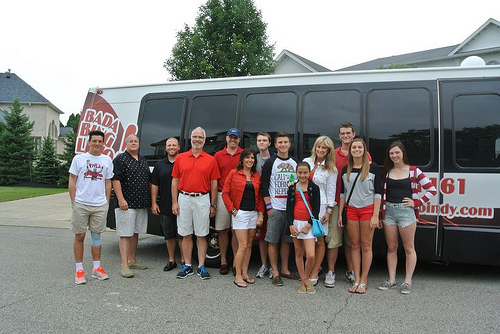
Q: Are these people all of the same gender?
A: No, they are both male and female.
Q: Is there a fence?
A: No, there are no fences.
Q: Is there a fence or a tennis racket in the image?
A: No, there are no fences or rackets.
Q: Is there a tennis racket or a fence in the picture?
A: No, there are no fences or rackets.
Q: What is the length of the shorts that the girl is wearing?
A: The shorts are short.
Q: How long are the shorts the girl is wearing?
A: The shorts are short.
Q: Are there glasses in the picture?
A: No, there are no glasses.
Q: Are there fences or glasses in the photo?
A: No, there are no glasses or fences.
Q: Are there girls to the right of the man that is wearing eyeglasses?
A: Yes, there is a girl to the right of the man.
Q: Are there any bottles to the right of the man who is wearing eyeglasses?
A: No, there is a girl to the right of the man.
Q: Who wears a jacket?
A: The girl wears a jacket.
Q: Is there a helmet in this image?
A: No, there are no helmets.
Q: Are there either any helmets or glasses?
A: No, there are no helmets or glasses.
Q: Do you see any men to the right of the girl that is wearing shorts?
A: Yes, there is a man to the right of the girl.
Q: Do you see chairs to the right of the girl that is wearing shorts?
A: No, there is a man to the right of the girl.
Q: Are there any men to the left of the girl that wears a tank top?
A: Yes, there is a man to the left of the girl.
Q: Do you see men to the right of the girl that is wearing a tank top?
A: No, the man is to the left of the girl.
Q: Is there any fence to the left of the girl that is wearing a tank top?
A: No, there is a man to the left of the girl.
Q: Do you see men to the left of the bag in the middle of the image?
A: Yes, there is a man to the left of the handbag.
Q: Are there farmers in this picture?
A: No, there are no farmers.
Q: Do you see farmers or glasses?
A: No, there are no farmers or glasses.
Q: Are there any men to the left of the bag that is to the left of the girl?
A: Yes, there is a man to the left of the handbag.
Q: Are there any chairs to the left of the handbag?
A: No, there is a man to the left of the handbag.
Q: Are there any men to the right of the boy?
A: Yes, there is a man to the right of the boy.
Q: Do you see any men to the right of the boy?
A: Yes, there is a man to the right of the boy.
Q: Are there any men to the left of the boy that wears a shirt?
A: No, the man is to the right of the boy.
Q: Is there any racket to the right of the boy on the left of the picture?
A: No, there is a man to the right of the boy.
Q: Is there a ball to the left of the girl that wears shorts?
A: No, there is a man to the left of the girl.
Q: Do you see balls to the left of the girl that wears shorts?
A: No, there is a man to the left of the girl.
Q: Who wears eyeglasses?
A: The man wears eyeglasses.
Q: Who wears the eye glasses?
A: The man wears eyeglasses.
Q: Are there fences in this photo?
A: No, there are no fences.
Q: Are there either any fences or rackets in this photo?
A: No, there are no fences or rackets.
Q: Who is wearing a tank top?
A: The girl is wearing a tank top.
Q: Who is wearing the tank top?
A: The girl is wearing a tank top.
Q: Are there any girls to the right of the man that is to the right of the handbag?
A: Yes, there is a girl to the right of the man.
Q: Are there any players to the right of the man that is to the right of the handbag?
A: No, there is a girl to the right of the man.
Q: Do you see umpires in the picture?
A: No, there are no umpires.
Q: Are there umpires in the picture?
A: No, there are no umpires.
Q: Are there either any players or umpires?
A: No, there are no umpires or players.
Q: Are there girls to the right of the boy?
A: Yes, there is a girl to the right of the boy.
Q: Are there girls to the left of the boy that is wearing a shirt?
A: No, the girl is to the right of the boy.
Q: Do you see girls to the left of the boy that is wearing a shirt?
A: No, the girl is to the right of the boy.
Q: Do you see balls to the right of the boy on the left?
A: No, there is a girl to the right of the boy.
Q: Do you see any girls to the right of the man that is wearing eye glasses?
A: Yes, there is a girl to the right of the man.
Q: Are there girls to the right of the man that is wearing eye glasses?
A: Yes, there is a girl to the right of the man.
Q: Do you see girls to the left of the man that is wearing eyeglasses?
A: No, the girl is to the right of the man.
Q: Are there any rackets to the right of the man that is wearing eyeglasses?
A: No, there is a girl to the right of the man.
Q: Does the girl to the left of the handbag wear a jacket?
A: Yes, the girl wears a jacket.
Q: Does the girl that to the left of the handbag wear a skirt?
A: No, the girl wears a jacket.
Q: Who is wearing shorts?
A: The girl is wearing shorts.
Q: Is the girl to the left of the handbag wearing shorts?
A: Yes, the girl is wearing shorts.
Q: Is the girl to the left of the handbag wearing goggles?
A: No, the girl is wearing shorts.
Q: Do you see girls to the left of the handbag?
A: Yes, there is a girl to the left of the handbag.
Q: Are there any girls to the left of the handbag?
A: Yes, there is a girl to the left of the handbag.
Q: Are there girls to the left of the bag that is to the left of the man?
A: Yes, there is a girl to the left of the handbag.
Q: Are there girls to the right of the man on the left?
A: Yes, there is a girl to the right of the man.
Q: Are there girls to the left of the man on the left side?
A: No, the girl is to the right of the man.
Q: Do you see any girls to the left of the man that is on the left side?
A: No, the girl is to the right of the man.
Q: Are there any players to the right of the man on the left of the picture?
A: No, there is a girl to the right of the man.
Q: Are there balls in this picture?
A: No, there are no balls.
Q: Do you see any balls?
A: No, there are no balls.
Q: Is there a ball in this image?
A: No, there are no balls.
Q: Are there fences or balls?
A: No, there are no balls or fences.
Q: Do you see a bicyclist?
A: No, there are no cyclists.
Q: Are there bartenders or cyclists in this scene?
A: No, there are no cyclists or bartenders.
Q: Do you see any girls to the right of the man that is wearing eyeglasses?
A: Yes, there is a girl to the right of the man.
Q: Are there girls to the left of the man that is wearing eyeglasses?
A: No, the girl is to the right of the man.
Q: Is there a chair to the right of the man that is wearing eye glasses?
A: No, there is a girl to the right of the man.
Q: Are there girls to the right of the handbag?
A: Yes, there is a girl to the right of the handbag.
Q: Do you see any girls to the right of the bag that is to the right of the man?
A: Yes, there is a girl to the right of the handbag.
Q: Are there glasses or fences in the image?
A: No, there are no fences or glasses.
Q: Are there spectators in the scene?
A: No, there are no spectators.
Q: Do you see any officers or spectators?
A: No, there are no spectators or officers.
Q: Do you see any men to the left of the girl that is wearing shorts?
A: Yes, there is a man to the left of the girl.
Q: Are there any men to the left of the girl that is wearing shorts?
A: Yes, there is a man to the left of the girl.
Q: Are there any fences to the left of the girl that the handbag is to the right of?
A: No, there is a man to the left of the girl.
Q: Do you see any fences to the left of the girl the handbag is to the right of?
A: No, there is a man to the left of the girl.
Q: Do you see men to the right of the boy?
A: Yes, there is a man to the right of the boy.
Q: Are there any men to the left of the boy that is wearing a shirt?
A: No, the man is to the right of the boy.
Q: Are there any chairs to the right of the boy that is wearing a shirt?
A: No, there is a man to the right of the boy.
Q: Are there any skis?
A: No, there are no skis.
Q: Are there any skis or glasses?
A: No, there are no skis or glasses.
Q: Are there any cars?
A: No, there are no cars.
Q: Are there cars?
A: No, there are no cars.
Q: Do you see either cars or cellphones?
A: No, there are no cars or cellphones.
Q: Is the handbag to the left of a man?
A: No, the handbag is to the right of a man.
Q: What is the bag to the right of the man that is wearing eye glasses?
A: The bag is a handbag.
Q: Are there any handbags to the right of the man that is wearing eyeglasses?
A: Yes, there is a handbag to the right of the man.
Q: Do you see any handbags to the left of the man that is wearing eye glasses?
A: No, the handbag is to the right of the man.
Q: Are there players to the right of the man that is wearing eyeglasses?
A: No, there is a handbag to the right of the man.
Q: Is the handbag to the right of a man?
A: Yes, the handbag is to the right of a man.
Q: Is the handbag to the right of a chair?
A: No, the handbag is to the right of a man.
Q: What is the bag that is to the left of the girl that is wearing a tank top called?
A: The bag is a handbag.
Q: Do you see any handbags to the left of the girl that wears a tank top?
A: Yes, there is a handbag to the left of the girl.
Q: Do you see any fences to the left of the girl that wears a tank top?
A: No, there is a handbag to the left of the girl.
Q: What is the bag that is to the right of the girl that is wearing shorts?
A: The bag is a handbag.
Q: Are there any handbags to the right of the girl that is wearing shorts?
A: Yes, there is a handbag to the right of the girl.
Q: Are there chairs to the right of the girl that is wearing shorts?
A: No, there is a handbag to the right of the girl.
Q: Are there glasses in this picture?
A: No, there are no glasses.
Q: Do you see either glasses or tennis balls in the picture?
A: No, there are no glasses or tennis balls.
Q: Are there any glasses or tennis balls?
A: No, there are no glasses or tennis balls.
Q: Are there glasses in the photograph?
A: No, there are no glasses.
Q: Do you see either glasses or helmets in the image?
A: No, there are no glasses or helmets.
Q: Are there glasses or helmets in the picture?
A: No, there are no glasses or helmets.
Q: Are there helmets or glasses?
A: No, there are no glasses or helmets.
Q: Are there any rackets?
A: No, there are no rackets.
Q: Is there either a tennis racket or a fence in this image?
A: No, there are no rackets or fences.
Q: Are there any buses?
A: Yes, there is a bus.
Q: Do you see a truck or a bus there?
A: Yes, there is a bus.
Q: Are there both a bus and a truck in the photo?
A: No, there is a bus but no trucks.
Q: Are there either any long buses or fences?
A: Yes, there is a long bus.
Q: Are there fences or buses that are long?
A: Yes, the bus is long.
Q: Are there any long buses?
A: Yes, there is a long bus.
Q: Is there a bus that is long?
A: Yes, there is a bus that is long.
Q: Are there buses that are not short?
A: Yes, there is a long bus.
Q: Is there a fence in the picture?
A: No, there are no fences.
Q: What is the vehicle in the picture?
A: The vehicle is a bus.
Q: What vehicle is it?
A: The vehicle is a bus.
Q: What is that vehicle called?
A: This is a bus.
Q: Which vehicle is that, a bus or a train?
A: This is a bus.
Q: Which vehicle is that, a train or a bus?
A: This is a bus.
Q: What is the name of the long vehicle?
A: The vehicle is a bus.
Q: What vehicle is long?
A: The vehicle is a bus.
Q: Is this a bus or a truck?
A: This is a bus.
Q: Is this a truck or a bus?
A: This is a bus.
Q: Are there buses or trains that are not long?
A: No, there is a bus but it is long.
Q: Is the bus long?
A: Yes, the bus is long.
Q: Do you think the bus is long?
A: Yes, the bus is long.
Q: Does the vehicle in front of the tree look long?
A: Yes, the bus is long.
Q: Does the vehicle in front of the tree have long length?
A: Yes, the bus is long.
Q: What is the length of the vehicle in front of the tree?
A: The bus is long.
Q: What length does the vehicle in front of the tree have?
A: The bus has long length.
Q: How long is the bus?
A: The bus is long.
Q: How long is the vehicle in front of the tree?
A: The bus is long.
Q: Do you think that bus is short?
A: No, the bus is long.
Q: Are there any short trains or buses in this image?
A: No, there is a bus but it is long.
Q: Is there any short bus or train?
A: No, there is a bus but it is long.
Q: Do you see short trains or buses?
A: No, there is a bus but it is long.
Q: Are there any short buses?
A: No, there is a bus but it is long.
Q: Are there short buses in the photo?
A: No, there is a bus but it is long.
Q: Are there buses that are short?
A: No, there is a bus but it is long.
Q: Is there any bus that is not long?
A: No, there is a bus but it is long.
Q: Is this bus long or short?
A: The bus is long.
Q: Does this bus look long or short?
A: The bus is long.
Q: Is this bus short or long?
A: The bus is long.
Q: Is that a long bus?
A: Yes, that is a long bus.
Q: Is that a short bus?
A: No, that is a long bus.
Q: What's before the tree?
A: The bus is in front of the tree.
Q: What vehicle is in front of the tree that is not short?
A: The vehicle is a bus.